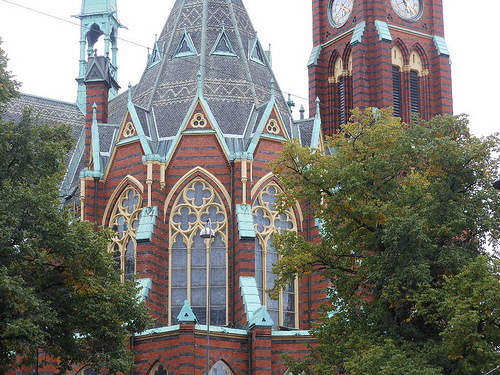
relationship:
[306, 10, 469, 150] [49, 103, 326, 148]
tower on roof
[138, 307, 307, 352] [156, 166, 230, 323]
balcony outside window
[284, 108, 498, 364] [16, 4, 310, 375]
tree fronting church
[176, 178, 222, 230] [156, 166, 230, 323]
circles on window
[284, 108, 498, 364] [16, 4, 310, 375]
tree in front of church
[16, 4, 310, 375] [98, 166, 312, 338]
church has windows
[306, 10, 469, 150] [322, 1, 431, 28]
tower has clocks